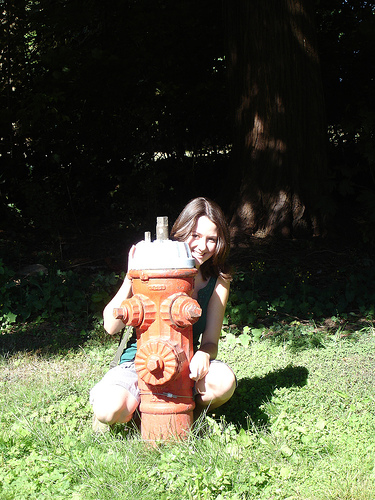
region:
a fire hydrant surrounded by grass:
[110, 210, 201, 447]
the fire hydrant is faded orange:
[110, 211, 200, 440]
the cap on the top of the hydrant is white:
[124, 211, 195, 268]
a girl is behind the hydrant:
[87, 196, 235, 437]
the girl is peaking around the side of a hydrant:
[113, 195, 225, 277]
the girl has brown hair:
[169, 196, 226, 279]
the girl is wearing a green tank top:
[90, 195, 236, 428]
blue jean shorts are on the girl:
[99, 355, 219, 397]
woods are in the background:
[4, 4, 369, 433]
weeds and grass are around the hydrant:
[3, 319, 372, 495]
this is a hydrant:
[143, 222, 184, 433]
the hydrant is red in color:
[145, 324, 173, 381]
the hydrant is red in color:
[147, 405, 167, 416]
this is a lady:
[192, 203, 220, 261]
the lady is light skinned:
[214, 310, 216, 322]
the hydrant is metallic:
[141, 290, 185, 346]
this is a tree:
[247, 112, 303, 220]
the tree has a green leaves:
[24, 43, 69, 76]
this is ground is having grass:
[223, 440, 327, 497]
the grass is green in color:
[245, 457, 297, 489]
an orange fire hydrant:
[112, 216, 198, 439]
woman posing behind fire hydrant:
[94, 193, 236, 427]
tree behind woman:
[217, 0, 352, 255]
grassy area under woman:
[0, 263, 374, 498]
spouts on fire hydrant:
[109, 294, 202, 388]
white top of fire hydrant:
[130, 215, 196, 266]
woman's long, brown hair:
[170, 195, 224, 279]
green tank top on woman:
[121, 271, 220, 363]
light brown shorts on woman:
[96, 357, 237, 387]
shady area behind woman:
[3, 12, 370, 279]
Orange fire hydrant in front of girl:
[110, 215, 203, 444]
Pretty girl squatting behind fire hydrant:
[86, 195, 238, 433]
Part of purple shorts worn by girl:
[106, 361, 140, 394]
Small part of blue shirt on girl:
[121, 342, 143, 362]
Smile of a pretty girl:
[185, 232, 217, 266]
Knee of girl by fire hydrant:
[90, 395, 127, 427]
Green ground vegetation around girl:
[0, 341, 374, 499]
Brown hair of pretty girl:
[170, 194, 226, 279]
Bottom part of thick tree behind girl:
[226, 91, 321, 272]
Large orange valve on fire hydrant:
[133, 336, 183, 390]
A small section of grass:
[246, 335, 371, 488]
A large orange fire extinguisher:
[120, 236, 200, 447]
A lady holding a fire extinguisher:
[93, 201, 240, 436]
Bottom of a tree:
[231, 36, 345, 258]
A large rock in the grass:
[8, 259, 57, 294]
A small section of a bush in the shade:
[15, 21, 155, 182]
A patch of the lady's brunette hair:
[199, 196, 223, 221]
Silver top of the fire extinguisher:
[125, 218, 193, 270]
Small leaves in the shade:
[278, 272, 373, 315]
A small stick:
[308, 244, 352, 258]